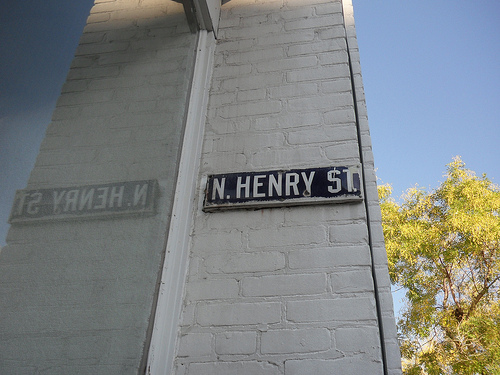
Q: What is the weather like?
A: It is cloudless.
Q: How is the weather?
A: It is cloudless.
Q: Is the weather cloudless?
A: Yes, it is cloudless.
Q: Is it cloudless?
A: Yes, it is cloudless.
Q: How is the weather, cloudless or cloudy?
A: It is cloudless.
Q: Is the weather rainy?
A: No, it is cloudless.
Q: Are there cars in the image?
A: No, there are no cars.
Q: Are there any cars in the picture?
A: No, there are no cars.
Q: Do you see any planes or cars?
A: No, there are no cars or planes.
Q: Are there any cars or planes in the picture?
A: No, there are no cars or planes.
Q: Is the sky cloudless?
A: Yes, the sky is cloudless.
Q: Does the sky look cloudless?
A: Yes, the sky is cloudless.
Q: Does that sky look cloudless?
A: Yes, the sky is cloudless.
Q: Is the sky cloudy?
A: No, the sky is cloudless.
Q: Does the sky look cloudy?
A: No, the sky is cloudless.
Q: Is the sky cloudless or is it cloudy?
A: The sky is cloudless.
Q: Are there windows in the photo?
A: Yes, there is a window.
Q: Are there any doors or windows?
A: Yes, there is a window.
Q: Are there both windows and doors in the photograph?
A: No, there is a window but no doors.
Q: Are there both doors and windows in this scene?
A: No, there is a window but no doors.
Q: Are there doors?
A: No, there are no doors.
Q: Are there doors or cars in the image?
A: No, there are no doors or cars.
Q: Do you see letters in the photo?
A: Yes, there are letters.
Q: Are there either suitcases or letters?
A: Yes, there are letters.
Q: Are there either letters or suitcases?
A: Yes, there are letters.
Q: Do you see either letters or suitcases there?
A: Yes, there are letters.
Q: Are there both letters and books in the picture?
A: No, there are letters but no books.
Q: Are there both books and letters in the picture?
A: No, there are letters but no books.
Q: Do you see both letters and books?
A: No, there are letters but no books.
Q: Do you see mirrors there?
A: No, there are no mirrors.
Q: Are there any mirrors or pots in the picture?
A: No, there are no mirrors or pots.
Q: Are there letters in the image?
A: Yes, there are letters.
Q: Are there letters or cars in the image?
A: Yes, there are letters.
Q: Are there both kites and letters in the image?
A: No, there are letters but no kites.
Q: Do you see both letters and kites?
A: No, there are letters but no kites.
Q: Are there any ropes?
A: No, there are no ropes.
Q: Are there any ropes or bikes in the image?
A: No, there are no ropes or bikes.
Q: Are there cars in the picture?
A: No, there are no cars.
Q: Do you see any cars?
A: No, there are no cars.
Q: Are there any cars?
A: No, there are no cars.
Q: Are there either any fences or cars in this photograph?
A: No, there are no cars or fences.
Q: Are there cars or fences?
A: No, there are no cars or fences.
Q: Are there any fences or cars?
A: No, there are no cars or fences.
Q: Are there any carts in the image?
A: No, there are no carts.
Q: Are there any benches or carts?
A: No, there are no carts or benches.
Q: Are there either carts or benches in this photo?
A: No, there are no carts or benches.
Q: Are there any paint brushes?
A: No, there are no paint brushes.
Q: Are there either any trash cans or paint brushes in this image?
A: No, there are no paint brushes or trash cans.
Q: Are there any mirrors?
A: No, there are no mirrors.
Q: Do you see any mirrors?
A: No, there are no mirrors.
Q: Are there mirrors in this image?
A: No, there are no mirrors.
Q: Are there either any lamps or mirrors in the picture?
A: No, there are no mirrors or lamps.